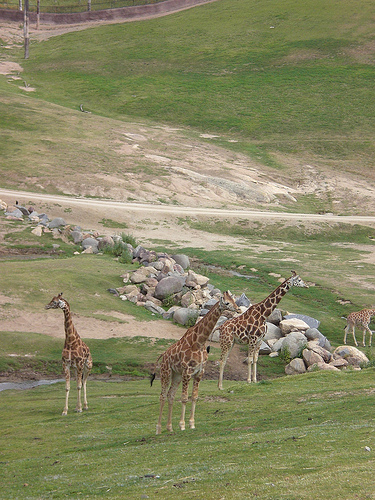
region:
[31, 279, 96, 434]
giraffe standing in green grass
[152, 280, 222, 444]
giraffe standing in green grass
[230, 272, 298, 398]
giraffe standing in green grass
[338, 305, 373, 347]
giraffe standing in green grass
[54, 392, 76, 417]
white leg of giraffe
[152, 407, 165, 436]
white leg of giraffe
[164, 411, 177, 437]
white leg of giraffe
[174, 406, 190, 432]
white leg of giraffe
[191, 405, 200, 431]
white leg of giraffe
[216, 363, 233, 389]
white leg of giraffe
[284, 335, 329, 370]
Group of large grey rocks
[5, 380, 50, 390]
Stream of flowing water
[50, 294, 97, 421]
Large tan and brown giraffe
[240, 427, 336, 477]
short light green grass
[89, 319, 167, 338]
Area of light brown sand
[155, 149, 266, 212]
Large dirt pile area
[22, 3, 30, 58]
Base of long thin tree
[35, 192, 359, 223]
Long dirt roadway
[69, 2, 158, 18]
Long concrete grey wall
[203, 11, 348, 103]
Small grass hill area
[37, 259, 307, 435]
Three animals are in the foreground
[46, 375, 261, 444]
Animals are standing on grass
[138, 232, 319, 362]
A pile of stones are in the background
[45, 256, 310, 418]
Animal has brown spots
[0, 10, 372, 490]
Photo was taken outside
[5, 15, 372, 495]
Photo was taken in the daytime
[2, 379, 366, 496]
Grass in the foreground is green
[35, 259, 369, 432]
Four african giraffes are in this image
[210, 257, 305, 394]
A side view of an african giraffe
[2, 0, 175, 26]
A fence is in the background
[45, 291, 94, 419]
a white and brown spotted giraffe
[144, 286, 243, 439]
a white and brown spotted giraffe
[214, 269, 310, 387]
a white and brown spotted giraffe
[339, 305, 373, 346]
a white and brown spotted giraffe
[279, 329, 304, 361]
a large grey boulder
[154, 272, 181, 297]
a large grey bouldera large grey boulder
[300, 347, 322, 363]
a large grey boulder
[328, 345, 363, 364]
a large grey boulder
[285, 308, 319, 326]
a large grey boulder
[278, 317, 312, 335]
a large grey boulder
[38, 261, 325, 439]
Three giraffes standing on slope of hill.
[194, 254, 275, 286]
Water running in a small stream.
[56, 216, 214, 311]
Piles of rocks stacked in a line along field.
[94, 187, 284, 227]
Road running along field with giraffes.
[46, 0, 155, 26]
Half wall with fence around enclosure.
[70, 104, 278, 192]
Patchy grass on slop of hill.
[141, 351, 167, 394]
Long brown tail of giraffe with black tip.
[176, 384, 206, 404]
Two front knees on giraffe.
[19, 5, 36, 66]
Bottom of post standing in enclosure.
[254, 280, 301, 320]
Long brown and white neck of giraffe.